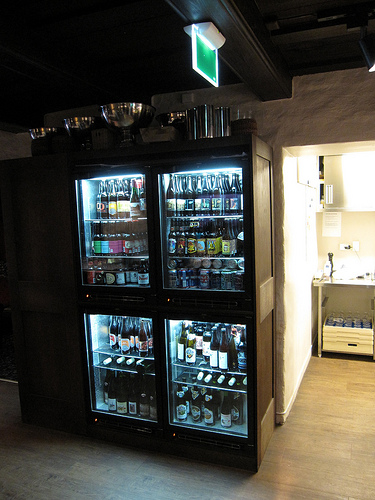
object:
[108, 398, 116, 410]
label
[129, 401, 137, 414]
white label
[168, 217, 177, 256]
bottle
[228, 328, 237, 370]
bottle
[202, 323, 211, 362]
bottle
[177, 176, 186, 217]
bottle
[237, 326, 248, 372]
bottle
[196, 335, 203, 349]
white label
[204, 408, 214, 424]
white label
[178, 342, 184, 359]
white label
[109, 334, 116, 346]
white label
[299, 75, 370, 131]
wall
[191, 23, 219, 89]
sign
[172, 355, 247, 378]
shelf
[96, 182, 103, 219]
beer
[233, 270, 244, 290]
cans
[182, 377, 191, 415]
bottle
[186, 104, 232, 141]
metal pot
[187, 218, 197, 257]
bottles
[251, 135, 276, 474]
door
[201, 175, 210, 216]
bottle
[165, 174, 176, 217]
bottle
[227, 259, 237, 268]
cans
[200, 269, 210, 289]
can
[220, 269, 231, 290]
can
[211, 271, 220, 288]
can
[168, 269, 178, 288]
can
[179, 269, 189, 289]
can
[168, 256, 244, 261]
shelf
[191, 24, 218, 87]
light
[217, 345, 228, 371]
stop sign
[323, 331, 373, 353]
wooden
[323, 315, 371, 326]
items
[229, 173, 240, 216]
bottle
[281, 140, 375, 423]
doorway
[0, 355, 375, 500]
floor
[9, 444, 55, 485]
floor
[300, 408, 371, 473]
wood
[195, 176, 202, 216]
bottle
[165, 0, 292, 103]
beams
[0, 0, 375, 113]
ceiling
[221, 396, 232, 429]
bottle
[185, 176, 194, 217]
bottle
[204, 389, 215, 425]
bottle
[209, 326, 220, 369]
bottle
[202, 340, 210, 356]
white label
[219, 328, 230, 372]
bottle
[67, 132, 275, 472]
cooler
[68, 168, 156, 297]
door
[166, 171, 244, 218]
beverages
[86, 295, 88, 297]
light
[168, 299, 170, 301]
light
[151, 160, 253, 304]
door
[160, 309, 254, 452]
door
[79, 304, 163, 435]
door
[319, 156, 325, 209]
cabinet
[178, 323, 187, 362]
bottle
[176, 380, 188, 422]
bottle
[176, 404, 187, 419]
lable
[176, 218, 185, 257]
bottles